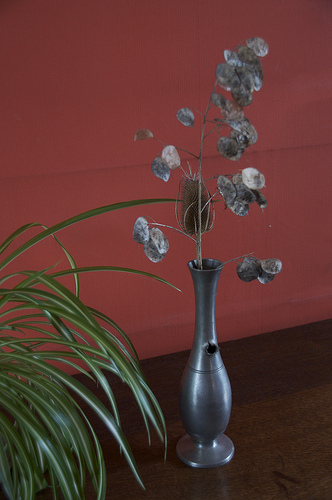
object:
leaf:
[260, 256, 284, 277]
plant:
[129, 30, 287, 293]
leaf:
[161, 144, 182, 171]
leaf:
[143, 226, 173, 267]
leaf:
[174, 104, 197, 129]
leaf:
[246, 36, 270, 57]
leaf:
[229, 69, 255, 108]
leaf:
[214, 63, 243, 90]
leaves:
[0, 392, 81, 500]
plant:
[0, 193, 199, 500]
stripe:
[75, 383, 108, 423]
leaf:
[0, 396, 80, 500]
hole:
[204, 341, 219, 357]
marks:
[264, 445, 303, 498]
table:
[77, 329, 332, 500]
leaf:
[130, 215, 151, 245]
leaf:
[240, 165, 267, 194]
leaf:
[234, 254, 262, 286]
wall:
[0, 3, 330, 373]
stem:
[195, 89, 212, 263]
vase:
[174, 255, 241, 477]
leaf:
[0, 193, 182, 278]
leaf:
[0, 271, 105, 337]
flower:
[131, 215, 152, 246]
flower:
[150, 153, 172, 184]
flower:
[175, 104, 196, 130]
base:
[176, 432, 236, 470]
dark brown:
[0, 376, 332, 500]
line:
[185, 361, 225, 376]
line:
[0, 139, 332, 183]